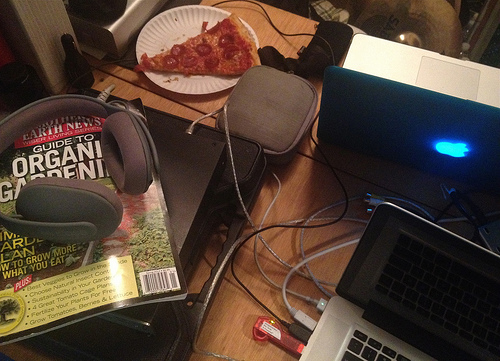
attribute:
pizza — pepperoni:
[131, 12, 262, 76]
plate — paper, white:
[134, 5, 260, 95]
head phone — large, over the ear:
[0, 93, 161, 244]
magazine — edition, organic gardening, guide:
[1, 96, 189, 347]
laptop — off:
[296, 200, 500, 360]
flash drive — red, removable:
[251, 315, 307, 359]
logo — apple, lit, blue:
[435, 140, 470, 159]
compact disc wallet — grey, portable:
[215, 64, 320, 165]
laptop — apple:
[314, 31, 497, 191]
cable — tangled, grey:
[280, 238, 363, 312]